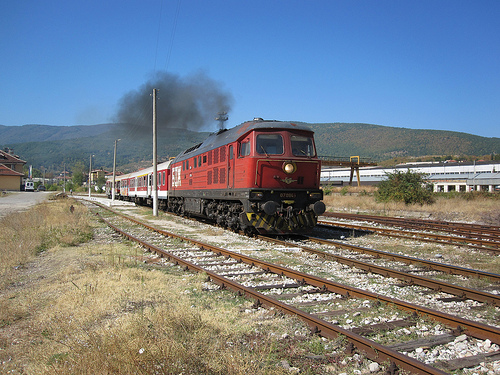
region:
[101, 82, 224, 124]
smoke emerging from diesel train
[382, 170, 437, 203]
a green bush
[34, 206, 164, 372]
brown grass along the side of the railroad track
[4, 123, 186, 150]
mountain range in the background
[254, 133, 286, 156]
window of diesel train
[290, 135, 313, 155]
window of train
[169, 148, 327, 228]
red diesel train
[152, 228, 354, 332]
railroad tracks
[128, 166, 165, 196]
red and white train car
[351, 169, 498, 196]
warehouses in the background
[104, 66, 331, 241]
Train puffing smoke.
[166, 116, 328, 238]
Red front car of train.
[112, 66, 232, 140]
Black smoke hovering in the air.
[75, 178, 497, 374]
Train tracks with stones between the rails.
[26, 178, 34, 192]
Parked van.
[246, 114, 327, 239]
Front of train with headlight on.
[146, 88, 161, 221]
Tall metal light pole.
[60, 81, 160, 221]
Row of four light poles.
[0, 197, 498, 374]
Dead, dry grass beside train tracks.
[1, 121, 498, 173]
Hills.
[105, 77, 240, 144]
Engine smoke from the train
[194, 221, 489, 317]
There's 4 parallel tracks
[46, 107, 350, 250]
Red and white train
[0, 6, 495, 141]
The sky is clear and blue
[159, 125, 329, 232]
Front cart of the train is red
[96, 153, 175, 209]
Back part of the train is white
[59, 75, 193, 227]
Three electric poles show in the picture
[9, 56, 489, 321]
The train is traveling towards right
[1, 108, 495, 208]
Mountains in the background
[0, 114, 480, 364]
Train traveling on the second track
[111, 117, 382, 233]
An old passenger train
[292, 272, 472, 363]
Brown steel rails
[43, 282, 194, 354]
Dried grassy ground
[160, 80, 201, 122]
Black steam smokes from the train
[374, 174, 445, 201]
A small bush by the fence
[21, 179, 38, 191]
A white van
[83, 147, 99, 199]
Tall lamp posts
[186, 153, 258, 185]
The color of the front is red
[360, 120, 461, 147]
There are mountain ranges in the distance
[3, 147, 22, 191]
A building structure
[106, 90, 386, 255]
Train moving ahead to destination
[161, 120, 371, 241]
Red Engine leads the cars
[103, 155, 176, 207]
White and red cars behind the engine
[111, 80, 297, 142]
Black smoke coming from the engine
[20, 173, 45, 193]
Parked van behind the train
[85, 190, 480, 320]
Four tracks for trains to travel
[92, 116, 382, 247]
3 cars with 1 engine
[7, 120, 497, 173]
Mountain landscape behind the train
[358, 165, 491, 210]
White buildings to the right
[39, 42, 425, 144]
Blue skies surround the land